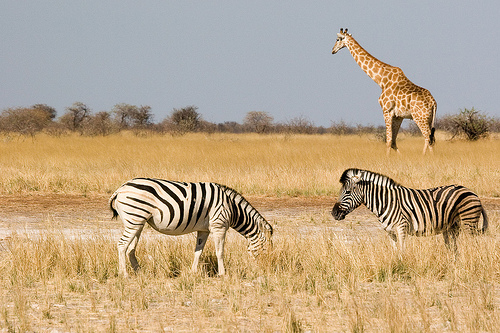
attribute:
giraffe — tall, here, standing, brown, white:
[332, 27, 438, 158]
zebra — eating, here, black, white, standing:
[331, 167, 489, 250]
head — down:
[249, 222, 275, 267]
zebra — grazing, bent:
[109, 178, 272, 280]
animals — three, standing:
[107, 28, 490, 278]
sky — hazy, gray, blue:
[1, 1, 498, 128]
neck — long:
[350, 44, 401, 87]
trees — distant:
[0, 102, 199, 138]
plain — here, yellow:
[0, 132, 499, 333]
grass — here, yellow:
[0, 135, 382, 168]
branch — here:
[82, 113, 91, 119]